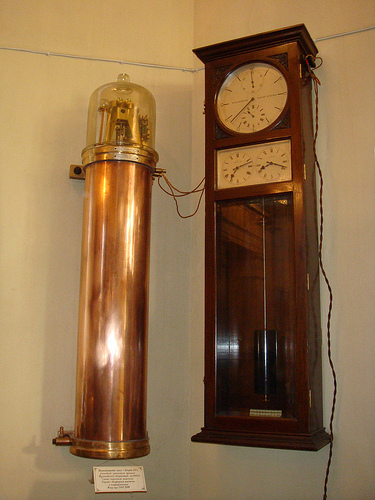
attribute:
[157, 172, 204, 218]
wires — copper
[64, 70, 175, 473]
capsule — bronze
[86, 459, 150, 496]
label — white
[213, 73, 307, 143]
time — displayed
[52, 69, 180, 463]
barometer — old, antique, copper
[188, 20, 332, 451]
case — wooden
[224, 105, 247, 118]
line — black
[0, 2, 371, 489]
wall — white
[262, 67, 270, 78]
line — black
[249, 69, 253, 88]
line — black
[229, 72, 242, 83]
line — black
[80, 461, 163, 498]
card — white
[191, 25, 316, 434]
clock — old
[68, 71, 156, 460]
capsule — long, bronze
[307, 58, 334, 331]
wire — thin, twisted, black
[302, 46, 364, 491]
wire — long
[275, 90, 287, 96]
line — black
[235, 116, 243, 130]
line — black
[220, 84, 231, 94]
line — black